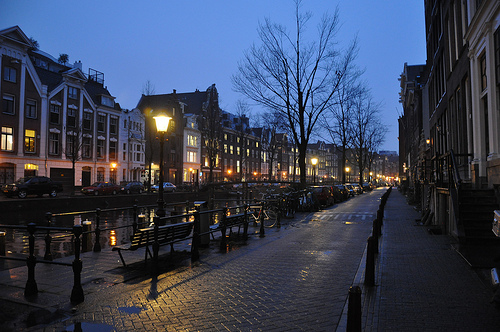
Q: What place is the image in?
A: It is at the road.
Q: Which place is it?
A: It is a road.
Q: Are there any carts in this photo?
A: No, there are no carts.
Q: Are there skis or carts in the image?
A: No, there are no carts or skis.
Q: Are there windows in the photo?
A: Yes, there is a window.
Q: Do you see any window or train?
A: Yes, there is a window.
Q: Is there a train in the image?
A: No, there are no trains.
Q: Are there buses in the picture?
A: No, there are no buses.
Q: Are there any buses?
A: No, there are no buses.